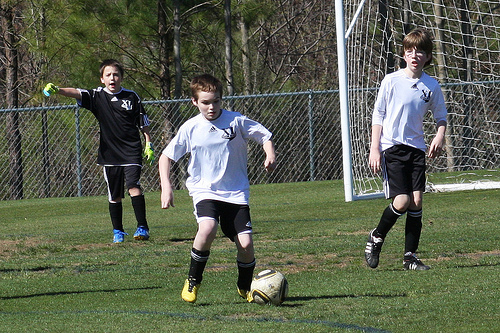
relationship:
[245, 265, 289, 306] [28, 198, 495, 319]
ball on ground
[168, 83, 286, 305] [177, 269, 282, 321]
boy wearing sneakers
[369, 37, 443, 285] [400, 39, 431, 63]
boy wearing glasses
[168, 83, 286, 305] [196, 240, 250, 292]
boy wearing socks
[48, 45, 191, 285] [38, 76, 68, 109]
boy wearing gloves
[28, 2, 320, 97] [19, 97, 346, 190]
trees behind gate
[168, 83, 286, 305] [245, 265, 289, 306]
boy kicking ball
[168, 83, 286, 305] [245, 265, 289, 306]
boy near ball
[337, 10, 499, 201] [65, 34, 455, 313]
goal behind kids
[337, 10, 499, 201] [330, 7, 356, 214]
goal has post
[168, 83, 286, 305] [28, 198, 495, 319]
boy on field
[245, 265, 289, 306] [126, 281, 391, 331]
ball on grass